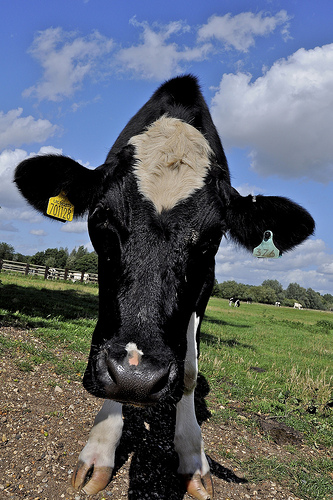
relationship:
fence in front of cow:
[2, 257, 85, 282] [47, 264, 61, 279]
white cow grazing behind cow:
[292, 300, 303, 310] [15, 76, 308, 497]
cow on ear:
[15, 76, 308, 497] [230, 195, 314, 259]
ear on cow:
[230, 195, 314, 259] [15, 76, 308, 497]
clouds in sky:
[195, 4, 293, 53] [0, 0, 331, 233]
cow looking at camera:
[15, 76, 308, 497] [6, 386, 47, 425]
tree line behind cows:
[211, 278, 331, 311] [13, 72, 314, 498]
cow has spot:
[15, 76, 308, 497] [129, 119, 211, 207]